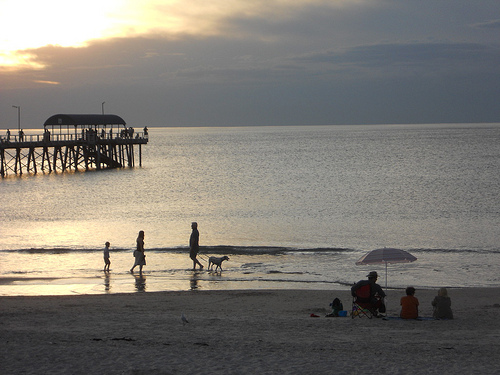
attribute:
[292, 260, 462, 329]
people — facing ocean, watching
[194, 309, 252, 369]
beach — at sunset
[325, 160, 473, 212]
ocean — looking like silver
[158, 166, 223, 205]
water — calm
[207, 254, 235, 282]
dog — white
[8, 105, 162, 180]
pier — overlooking water, covered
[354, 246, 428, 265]
umbrella — white, large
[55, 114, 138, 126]
roof — black, canopy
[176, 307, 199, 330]
seagull — on sand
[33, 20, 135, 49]
sun — setting, shining on water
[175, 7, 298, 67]
clouds — dark, on the horizon